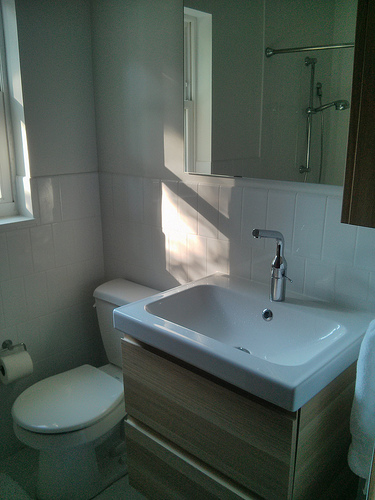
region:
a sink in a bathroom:
[17, 91, 354, 357]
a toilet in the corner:
[11, 267, 144, 479]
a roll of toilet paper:
[2, 331, 46, 390]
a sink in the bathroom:
[131, 267, 362, 402]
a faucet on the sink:
[240, 224, 295, 302]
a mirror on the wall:
[164, 9, 331, 198]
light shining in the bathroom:
[113, 117, 278, 292]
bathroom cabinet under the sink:
[112, 338, 276, 498]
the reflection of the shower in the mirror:
[261, 21, 366, 173]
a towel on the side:
[324, 291, 370, 478]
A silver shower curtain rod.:
[265, 43, 357, 55]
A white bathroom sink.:
[114, 272, 357, 410]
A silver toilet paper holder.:
[1, 338, 33, 373]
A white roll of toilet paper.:
[3, 352, 35, 384]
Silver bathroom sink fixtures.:
[249, 223, 297, 305]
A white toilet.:
[12, 276, 168, 498]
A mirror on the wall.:
[182, 3, 359, 181]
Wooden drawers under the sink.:
[118, 331, 371, 498]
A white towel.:
[345, 318, 373, 480]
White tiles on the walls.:
[0, 175, 374, 455]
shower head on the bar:
[300, 62, 348, 177]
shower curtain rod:
[266, 37, 372, 64]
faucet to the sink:
[245, 224, 305, 306]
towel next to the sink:
[343, 330, 373, 492]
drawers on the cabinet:
[99, 345, 287, 498]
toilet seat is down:
[14, 341, 124, 434]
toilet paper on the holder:
[4, 343, 32, 389]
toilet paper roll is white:
[0, 346, 38, 387]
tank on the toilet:
[86, 266, 155, 366]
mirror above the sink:
[178, 2, 371, 206]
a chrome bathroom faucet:
[250, 225, 295, 303]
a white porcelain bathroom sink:
[112, 272, 372, 409]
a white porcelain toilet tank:
[93, 276, 164, 368]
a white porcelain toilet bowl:
[13, 360, 129, 494]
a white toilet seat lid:
[9, 362, 124, 434]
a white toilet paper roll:
[1, 347, 35, 381]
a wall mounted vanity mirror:
[182, 3, 357, 189]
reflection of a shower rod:
[265, 41, 357, 54]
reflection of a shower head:
[296, 56, 348, 177]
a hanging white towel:
[347, 312, 373, 475]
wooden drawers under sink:
[119, 330, 359, 497]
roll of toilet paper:
[0, 354, 35, 384]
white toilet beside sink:
[8, 274, 160, 495]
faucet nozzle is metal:
[253, 228, 289, 303]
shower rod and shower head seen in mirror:
[265, 47, 349, 174]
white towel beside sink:
[345, 312, 373, 481]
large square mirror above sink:
[183, 1, 357, 188]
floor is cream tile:
[0, 423, 146, 498]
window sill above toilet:
[0, 0, 34, 226]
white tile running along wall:
[0, 171, 373, 458]